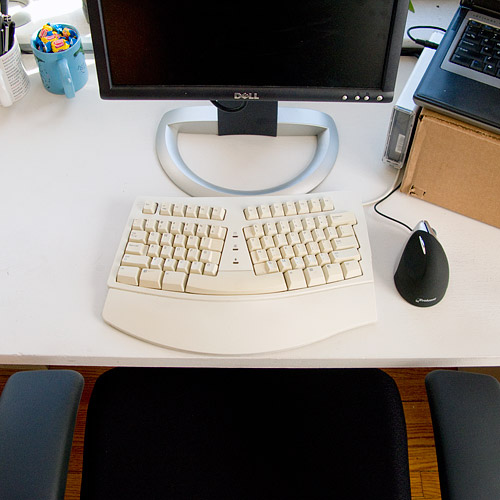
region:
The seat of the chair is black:
[142, 385, 333, 482]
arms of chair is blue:
[13, 398, 46, 464]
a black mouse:
[396, 244, 452, 311]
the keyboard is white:
[135, 203, 330, 310]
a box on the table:
[421, 131, 492, 219]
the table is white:
[12, 194, 77, 278]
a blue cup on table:
[23, 43, 87, 94]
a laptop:
[423, 41, 489, 113]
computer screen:
[101, 10, 415, 115]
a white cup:
[3, 53, 40, 100]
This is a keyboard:
[92, 182, 383, 354]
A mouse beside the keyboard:
[356, 200, 469, 309]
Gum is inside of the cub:
[17, 17, 97, 104]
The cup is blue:
[27, 13, 108, 117]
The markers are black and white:
[3, 15, 44, 138]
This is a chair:
[5, 364, 498, 499]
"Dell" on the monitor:
[201, 67, 278, 119]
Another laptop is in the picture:
[386, 2, 498, 128]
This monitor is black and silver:
[75, 2, 402, 214]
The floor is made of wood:
[1, 367, 498, 481]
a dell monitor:
[73, 2, 411, 146]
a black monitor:
[78, 1, 397, 190]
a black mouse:
[374, 118, 472, 318]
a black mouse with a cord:
[371, 164, 468, 309]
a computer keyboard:
[82, 179, 393, 360]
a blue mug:
[23, 15, 90, 100]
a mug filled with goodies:
[21, 17, 88, 109]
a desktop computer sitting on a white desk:
[76, 3, 451, 344]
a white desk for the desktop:
[23, 141, 104, 211]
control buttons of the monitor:
[334, 92, 390, 102]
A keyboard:
[121, 197, 354, 314]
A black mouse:
[390, 231, 464, 305]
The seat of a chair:
[106, 397, 396, 497]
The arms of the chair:
[11, 401, 68, 471]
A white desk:
[11, 132, 104, 216]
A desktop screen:
[108, 31, 407, 106]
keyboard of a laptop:
[419, 13, 496, 129]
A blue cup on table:
[25, 38, 105, 99]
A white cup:
[2, 58, 37, 103]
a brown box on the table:
[422, 134, 492, 217]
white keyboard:
[120, 193, 310, 350]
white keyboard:
[153, 211, 359, 457]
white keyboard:
[195, 265, 292, 359]